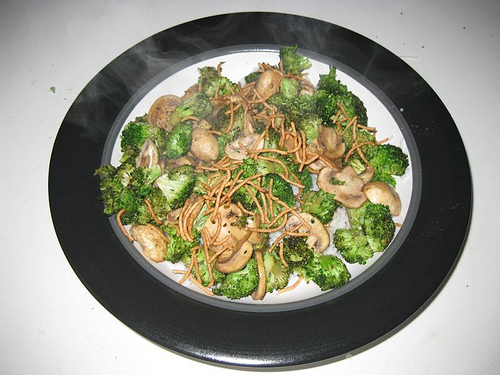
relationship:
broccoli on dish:
[100, 44, 406, 296] [46, 11, 472, 367]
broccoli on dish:
[365, 142, 407, 189] [46, 11, 472, 367]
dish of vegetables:
[38, 5, 486, 374] [333, 203, 396, 265]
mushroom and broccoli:
[317, 163, 365, 207] [332, 200, 396, 262]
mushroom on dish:
[241, 243, 270, 303] [46, 11, 472, 367]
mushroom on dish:
[224, 133, 264, 161] [46, 11, 472, 367]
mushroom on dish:
[205, 202, 250, 254] [46, 11, 472, 367]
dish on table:
[46, 11, 472, 367] [0, 0, 500, 374]